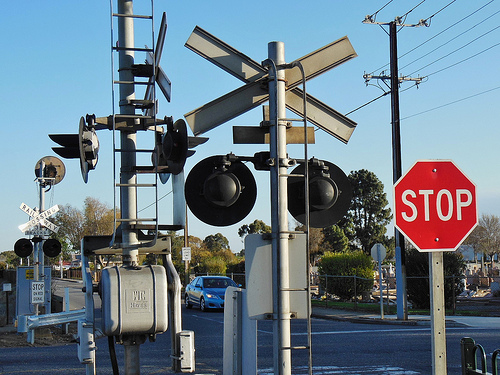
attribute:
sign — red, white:
[393, 157, 481, 252]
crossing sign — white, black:
[14, 196, 68, 238]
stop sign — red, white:
[396, 158, 480, 253]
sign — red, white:
[385, 146, 487, 271]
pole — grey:
[423, 250, 451, 374]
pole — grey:
[265, 39, 297, 373]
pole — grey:
[111, 1, 139, 261]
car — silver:
[179, 264, 251, 332]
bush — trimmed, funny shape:
[307, 245, 381, 302]